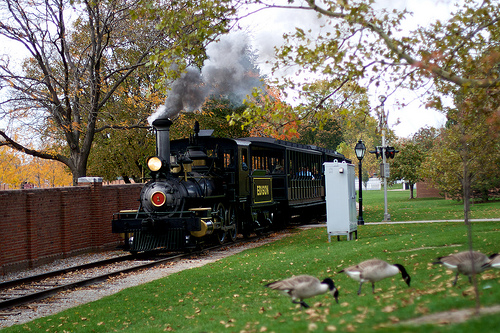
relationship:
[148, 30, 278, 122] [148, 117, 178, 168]
steam coming out of smoke stack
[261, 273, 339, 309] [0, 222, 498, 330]
birds standing in grass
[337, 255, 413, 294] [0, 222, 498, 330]
goose standing in grass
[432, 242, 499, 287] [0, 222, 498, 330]
goose standing in grass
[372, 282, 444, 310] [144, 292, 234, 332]
leaves on ground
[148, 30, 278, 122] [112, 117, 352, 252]
steam coming from train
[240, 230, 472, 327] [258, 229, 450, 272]
lawn with space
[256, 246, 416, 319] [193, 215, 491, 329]
birds on lawn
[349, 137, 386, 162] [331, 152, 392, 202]
light on a post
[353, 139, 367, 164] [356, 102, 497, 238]
light at rail crossing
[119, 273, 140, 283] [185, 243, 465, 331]
gravel near track